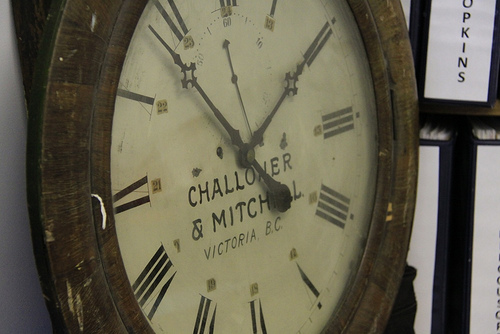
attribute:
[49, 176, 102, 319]
area — distressed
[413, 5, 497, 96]
paper — white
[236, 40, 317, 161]
hand — black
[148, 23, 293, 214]
hand — black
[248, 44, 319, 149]
hand — hour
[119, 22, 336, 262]
clock — old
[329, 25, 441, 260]
frame — wooden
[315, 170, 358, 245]
roman numerals — black